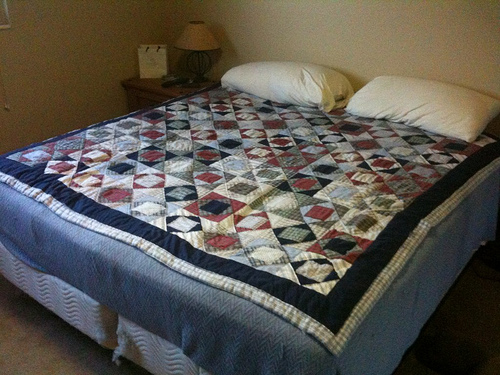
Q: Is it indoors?
A: Yes, it is indoors.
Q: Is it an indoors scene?
A: Yes, it is indoors.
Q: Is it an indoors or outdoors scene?
A: It is indoors.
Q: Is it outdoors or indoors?
A: It is indoors.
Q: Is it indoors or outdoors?
A: It is indoors.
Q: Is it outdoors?
A: No, it is indoors.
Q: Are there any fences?
A: No, there are no fences.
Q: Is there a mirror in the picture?
A: No, there are no mirrors.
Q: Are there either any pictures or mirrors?
A: No, there are no mirrors or pictures.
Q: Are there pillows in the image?
A: Yes, there is a pillow.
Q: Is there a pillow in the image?
A: Yes, there is a pillow.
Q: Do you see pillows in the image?
A: Yes, there is a pillow.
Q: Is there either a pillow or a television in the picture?
A: Yes, there is a pillow.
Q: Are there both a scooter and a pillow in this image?
A: No, there is a pillow but no scooters.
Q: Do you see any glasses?
A: No, there are no glasses.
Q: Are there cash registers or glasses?
A: No, there are no glasses or cash registers.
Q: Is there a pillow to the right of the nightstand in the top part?
A: Yes, there is a pillow to the right of the nightstand.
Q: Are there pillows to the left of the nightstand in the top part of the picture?
A: No, the pillow is to the right of the nightstand.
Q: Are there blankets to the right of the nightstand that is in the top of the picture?
A: No, there is a pillow to the right of the nightstand.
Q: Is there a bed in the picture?
A: Yes, there is a bed.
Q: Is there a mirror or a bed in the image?
A: Yes, there is a bed.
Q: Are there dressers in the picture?
A: No, there are no dressers.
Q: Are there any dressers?
A: No, there are no dressers.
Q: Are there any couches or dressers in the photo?
A: No, there are no dressers or couches.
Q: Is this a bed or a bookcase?
A: This is a bed.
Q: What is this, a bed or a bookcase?
A: This is a bed.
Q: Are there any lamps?
A: Yes, there is a lamp.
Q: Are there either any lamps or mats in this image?
A: Yes, there is a lamp.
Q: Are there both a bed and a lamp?
A: Yes, there are both a lamp and a bed.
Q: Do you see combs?
A: No, there are no combs.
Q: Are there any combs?
A: No, there are no combs.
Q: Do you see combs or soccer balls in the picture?
A: No, there are no combs or soccer balls.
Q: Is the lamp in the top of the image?
A: Yes, the lamp is in the top of the image.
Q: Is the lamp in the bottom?
A: No, the lamp is in the top of the image.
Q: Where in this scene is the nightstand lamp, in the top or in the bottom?
A: The lamp is in the top of the image.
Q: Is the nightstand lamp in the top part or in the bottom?
A: The lamp is in the top of the image.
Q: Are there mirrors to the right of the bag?
A: No, there is a lamp to the right of the bag.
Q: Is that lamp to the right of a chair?
A: No, the lamp is to the right of the bag.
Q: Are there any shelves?
A: No, there are no shelves.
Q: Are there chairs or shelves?
A: No, there are no shelves or chairs.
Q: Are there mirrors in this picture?
A: No, there are no mirrors.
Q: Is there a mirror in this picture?
A: No, there are no mirrors.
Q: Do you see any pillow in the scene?
A: Yes, there are pillows.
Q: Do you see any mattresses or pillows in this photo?
A: Yes, there are pillows.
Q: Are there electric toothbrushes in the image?
A: No, there are no electric toothbrushes.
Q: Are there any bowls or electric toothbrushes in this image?
A: No, there are no electric toothbrushes or bowls.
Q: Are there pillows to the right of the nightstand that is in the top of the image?
A: Yes, there are pillows to the right of the nightstand.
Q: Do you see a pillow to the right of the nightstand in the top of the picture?
A: Yes, there are pillows to the right of the nightstand.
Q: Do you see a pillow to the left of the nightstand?
A: No, the pillows are to the right of the nightstand.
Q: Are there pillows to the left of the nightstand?
A: No, the pillows are to the right of the nightstand.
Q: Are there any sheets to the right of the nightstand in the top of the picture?
A: No, there are pillows to the right of the nightstand.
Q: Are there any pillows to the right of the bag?
A: Yes, there are pillows to the right of the bag.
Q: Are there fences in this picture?
A: No, there are no fences.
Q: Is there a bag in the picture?
A: Yes, there is a bag.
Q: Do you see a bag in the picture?
A: Yes, there is a bag.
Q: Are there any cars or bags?
A: Yes, there is a bag.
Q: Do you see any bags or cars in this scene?
A: Yes, there is a bag.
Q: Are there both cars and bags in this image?
A: No, there is a bag but no cars.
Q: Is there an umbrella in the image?
A: No, there are no umbrellas.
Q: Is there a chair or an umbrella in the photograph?
A: No, there are no umbrellas or chairs.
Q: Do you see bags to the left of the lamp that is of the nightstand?
A: Yes, there is a bag to the left of the lamp.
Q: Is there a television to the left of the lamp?
A: No, there is a bag to the left of the lamp.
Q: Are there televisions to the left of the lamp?
A: No, there is a bag to the left of the lamp.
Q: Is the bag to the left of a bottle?
A: No, the bag is to the left of a lamp.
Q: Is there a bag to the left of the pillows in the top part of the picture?
A: Yes, there is a bag to the left of the pillows.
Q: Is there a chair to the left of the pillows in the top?
A: No, there is a bag to the left of the pillows.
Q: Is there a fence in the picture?
A: No, there are no fences.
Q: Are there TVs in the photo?
A: No, there are no tvs.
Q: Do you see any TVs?
A: No, there are no tvs.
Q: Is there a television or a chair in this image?
A: No, there are no televisions or chairs.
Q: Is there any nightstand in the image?
A: Yes, there is a nightstand.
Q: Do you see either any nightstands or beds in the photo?
A: Yes, there is a nightstand.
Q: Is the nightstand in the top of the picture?
A: Yes, the nightstand is in the top of the image.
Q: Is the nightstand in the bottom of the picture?
A: No, the nightstand is in the top of the image.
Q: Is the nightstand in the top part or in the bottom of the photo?
A: The nightstand is in the top of the image.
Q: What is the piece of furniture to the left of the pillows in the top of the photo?
A: The piece of furniture is a nightstand.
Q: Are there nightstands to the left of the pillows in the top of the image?
A: Yes, there is a nightstand to the left of the pillows.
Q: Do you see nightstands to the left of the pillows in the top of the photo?
A: Yes, there is a nightstand to the left of the pillows.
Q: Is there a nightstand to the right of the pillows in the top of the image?
A: No, the nightstand is to the left of the pillows.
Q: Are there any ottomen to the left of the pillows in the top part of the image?
A: No, there is a nightstand to the left of the pillows.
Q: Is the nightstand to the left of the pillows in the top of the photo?
A: Yes, the nightstand is to the left of the pillows.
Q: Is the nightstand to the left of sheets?
A: No, the nightstand is to the left of the pillows.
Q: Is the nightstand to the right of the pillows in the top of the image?
A: No, the nightstand is to the left of the pillows.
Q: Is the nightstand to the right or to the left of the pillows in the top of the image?
A: The nightstand is to the left of the pillows.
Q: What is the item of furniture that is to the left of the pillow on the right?
A: The piece of furniture is a nightstand.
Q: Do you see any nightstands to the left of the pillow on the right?
A: Yes, there is a nightstand to the left of the pillow.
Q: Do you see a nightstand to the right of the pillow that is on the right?
A: No, the nightstand is to the left of the pillow.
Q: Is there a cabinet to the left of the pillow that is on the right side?
A: No, there is a nightstand to the left of the pillow.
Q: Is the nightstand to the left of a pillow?
A: Yes, the nightstand is to the left of a pillow.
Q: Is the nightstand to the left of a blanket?
A: No, the nightstand is to the left of a pillow.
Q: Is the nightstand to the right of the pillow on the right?
A: No, the nightstand is to the left of the pillow.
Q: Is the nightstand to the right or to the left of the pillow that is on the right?
A: The nightstand is to the left of the pillow.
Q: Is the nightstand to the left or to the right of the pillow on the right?
A: The nightstand is to the left of the pillow.